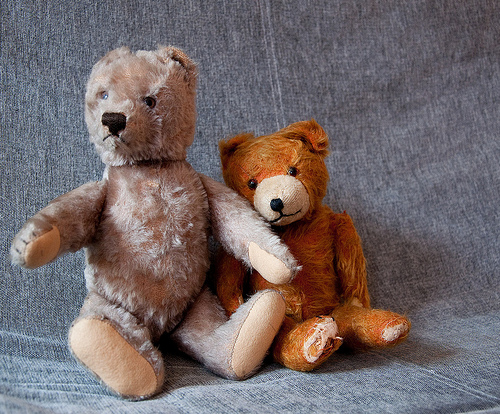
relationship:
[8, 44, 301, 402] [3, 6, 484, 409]
bear sitting couch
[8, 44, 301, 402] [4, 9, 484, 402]
bear in room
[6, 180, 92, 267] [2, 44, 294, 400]
arm of bear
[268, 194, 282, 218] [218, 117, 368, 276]
nose of bear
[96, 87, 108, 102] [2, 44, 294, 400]
eye of bear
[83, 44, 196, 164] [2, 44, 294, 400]
head of bear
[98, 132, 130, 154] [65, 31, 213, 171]
mouth of bear